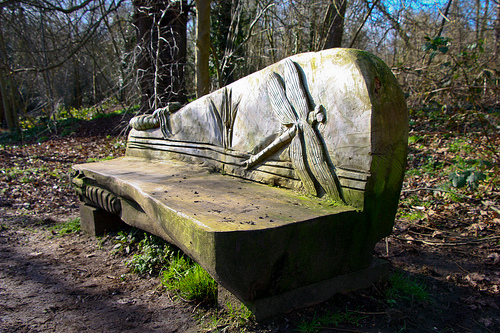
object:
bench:
[69, 47, 412, 323]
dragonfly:
[244, 58, 345, 204]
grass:
[163, 254, 217, 304]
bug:
[130, 104, 170, 137]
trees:
[320, 0, 348, 49]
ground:
[0, 113, 500, 323]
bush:
[4, 106, 121, 144]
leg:
[73, 205, 110, 237]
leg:
[217, 258, 390, 319]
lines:
[126, 135, 372, 191]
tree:
[0, 2, 25, 132]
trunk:
[0, 87, 14, 132]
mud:
[33, 274, 62, 296]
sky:
[3, 2, 496, 46]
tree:
[130, 0, 193, 112]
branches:
[150, 2, 173, 108]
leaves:
[422, 33, 451, 53]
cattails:
[206, 89, 243, 147]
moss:
[323, 194, 369, 212]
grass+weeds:
[134, 237, 165, 269]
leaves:
[447, 167, 486, 190]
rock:
[242, 218, 257, 224]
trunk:
[191, 3, 213, 93]